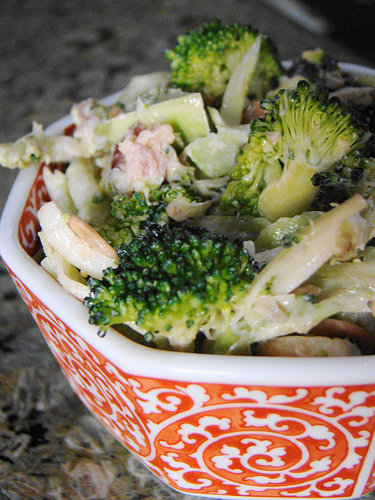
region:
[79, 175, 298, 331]
This is an asian dish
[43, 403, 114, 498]
This is a countertop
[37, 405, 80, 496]
The countertop is granite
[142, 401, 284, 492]
This is a picture of a design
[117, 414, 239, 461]
The design is orange and red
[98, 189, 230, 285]
This is dark green broccoli tops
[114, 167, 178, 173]
This is white meat chicken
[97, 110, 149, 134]
These are broccoli stems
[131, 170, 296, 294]
There is a lot of sauce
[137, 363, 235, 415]
The rim is white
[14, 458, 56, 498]
Marble top of a table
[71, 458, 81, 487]
Marble top of a table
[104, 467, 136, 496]
Marble top of a table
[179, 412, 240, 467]
White and orange design on bowl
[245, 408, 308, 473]
White and orange design on bowl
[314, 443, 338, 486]
White and orange design on bowl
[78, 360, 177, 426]
White and orange design on bowl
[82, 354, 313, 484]
White and orange design on bowl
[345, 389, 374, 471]
White and orange design on bowl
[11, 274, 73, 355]
White and orange design on bowl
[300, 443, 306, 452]
part of a plate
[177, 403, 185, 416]
edge of a plate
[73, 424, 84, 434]
part of a table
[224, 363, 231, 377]
edge of a bowl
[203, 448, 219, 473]
side of a bowl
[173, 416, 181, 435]
side of a bowl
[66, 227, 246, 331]
this is green brocolli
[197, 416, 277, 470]
this is a red and white pattern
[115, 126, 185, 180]
this is chicken meat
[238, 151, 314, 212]
this is a broccoli stalk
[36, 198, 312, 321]
this is a salad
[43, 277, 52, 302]
this is the color white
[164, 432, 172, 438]
this is the color orange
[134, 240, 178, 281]
this is a broccoli top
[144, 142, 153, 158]
this is the color pink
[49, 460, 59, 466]
this is the color gray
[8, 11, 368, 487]
Bowl sitting on a table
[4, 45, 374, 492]
Bowl with white rim and red and white design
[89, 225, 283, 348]
Large piece of broccoli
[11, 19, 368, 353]
Salad made with broccoli and pasta in white sauce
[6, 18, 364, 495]
Table with black, gray and brown design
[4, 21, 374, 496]
Salad in white and red bowl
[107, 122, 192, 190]
Piece of chicken in white sauce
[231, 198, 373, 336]
Piece of pasta in white sauce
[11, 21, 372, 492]
Bowl filled with broccoli salad sitting on table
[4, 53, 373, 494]
Heavy ceramic white and red bowl